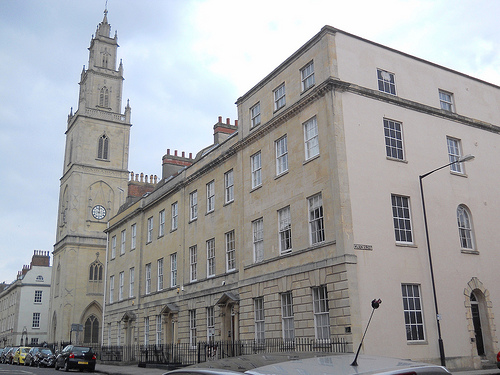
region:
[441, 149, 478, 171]
this is a street light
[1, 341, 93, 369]
this are vehicles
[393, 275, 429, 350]
this is a window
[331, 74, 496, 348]
this is a building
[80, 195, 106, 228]
this is a cloak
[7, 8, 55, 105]
this is the sky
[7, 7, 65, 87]
the sky is blue in color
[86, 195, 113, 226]
the cloak is white in color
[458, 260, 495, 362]
this is the building color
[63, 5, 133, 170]
this is the building tower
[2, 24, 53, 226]
this is the sky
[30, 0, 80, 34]
the sky is blue in color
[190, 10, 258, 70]
this is the sky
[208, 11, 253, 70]
the cloud is white in color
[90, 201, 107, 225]
this is a clock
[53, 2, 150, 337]
the building is tall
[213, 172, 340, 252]
the building has several windows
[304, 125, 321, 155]
the window has curtains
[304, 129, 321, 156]
the curtains are white in color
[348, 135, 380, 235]
the building is brown in color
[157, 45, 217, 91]
part of the clouds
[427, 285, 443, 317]
part of a post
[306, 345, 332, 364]
top of a car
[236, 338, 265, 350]
top of a fence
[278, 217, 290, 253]
part of a window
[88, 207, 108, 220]
part of a clock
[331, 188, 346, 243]
edge of a building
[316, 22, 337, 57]
top of a building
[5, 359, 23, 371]
part of a road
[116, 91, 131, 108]
part of a tip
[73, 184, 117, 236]
Clock on a tower.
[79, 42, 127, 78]
Cross on the building.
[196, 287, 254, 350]
Pillars around the doorway.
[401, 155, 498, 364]
The streetlight is black.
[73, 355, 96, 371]
Yellow license plate on the car.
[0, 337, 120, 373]
Row of cars in front of the building.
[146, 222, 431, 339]
The building is tan.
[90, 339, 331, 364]
A black fence in front of the building.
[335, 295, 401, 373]
The antenna is black.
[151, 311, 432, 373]
Silver car in front of the camera.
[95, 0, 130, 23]
A long pole on the tower.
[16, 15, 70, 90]
The sky is blue.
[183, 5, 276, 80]
The sky is white.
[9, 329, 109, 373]
Cars parked in front of the building.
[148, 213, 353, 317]
The building is tan.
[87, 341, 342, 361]
A black fence in front of the building.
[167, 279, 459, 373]
A silver car in front of the camera.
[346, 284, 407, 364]
The antenna is black.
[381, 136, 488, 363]
The streetlight is black.